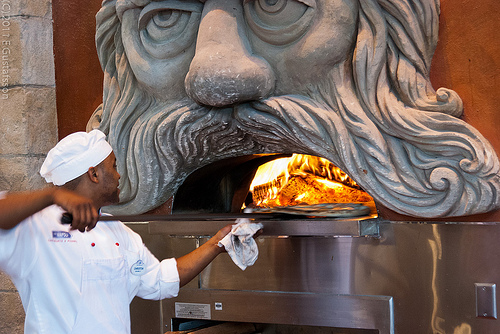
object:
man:
[0, 130, 261, 334]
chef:
[1, 128, 259, 334]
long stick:
[59, 212, 305, 225]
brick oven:
[56, 0, 498, 223]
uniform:
[26, 215, 106, 321]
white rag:
[216, 212, 268, 271]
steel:
[308, 256, 339, 283]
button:
[91, 243, 96, 247]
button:
[115, 243, 119, 246]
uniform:
[0, 203, 181, 334]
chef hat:
[37, 128, 114, 187]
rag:
[216, 207, 263, 271]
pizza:
[268, 202, 372, 217]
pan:
[111, 216, 370, 239]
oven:
[51, 0, 498, 334]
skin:
[105, 159, 112, 168]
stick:
[201, 208, 363, 219]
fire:
[250, 153, 377, 217]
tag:
[130, 260, 146, 277]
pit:
[356, 194, 369, 202]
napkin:
[217, 218, 264, 271]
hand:
[218, 220, 253, 252]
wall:
[54, 1, 484, 221]